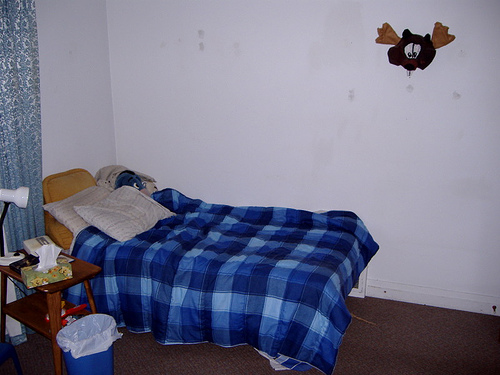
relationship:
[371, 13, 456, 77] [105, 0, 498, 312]
character on wall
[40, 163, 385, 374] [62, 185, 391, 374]
bed has a spread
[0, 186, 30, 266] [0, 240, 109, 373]
lamp on night stand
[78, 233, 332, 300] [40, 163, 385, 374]
edge on bed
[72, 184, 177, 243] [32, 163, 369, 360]
bed pillow on bed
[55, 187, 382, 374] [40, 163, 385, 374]
blue comforter on bed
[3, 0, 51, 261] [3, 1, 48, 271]
curtain on window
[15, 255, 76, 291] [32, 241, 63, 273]
box of tissue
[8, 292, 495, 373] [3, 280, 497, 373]
brown carpet on floor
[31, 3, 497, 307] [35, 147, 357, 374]
walls above bed